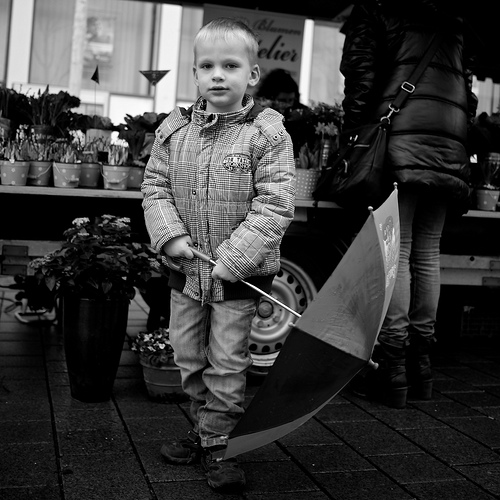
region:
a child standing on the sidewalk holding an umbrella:
[135, 16, 397, 453]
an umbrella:
[218, 205, 406, 475]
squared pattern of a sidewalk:
[335, 413, 485, 489]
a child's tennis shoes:
[158, 435, 243, 492]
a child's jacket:
[148, 102, 299, 283]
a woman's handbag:
[315, 110, 391, 210]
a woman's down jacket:
[350, 25, 477, 211]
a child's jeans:
[163, 296, 258, 442]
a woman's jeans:
[388, 200, 440, 343]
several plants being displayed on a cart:
[4, 87, 131, 184]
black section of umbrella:
[230, 313, 407, 442]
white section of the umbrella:
[303, 194, 418, 329]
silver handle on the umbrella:
[173, 224, 326, 337]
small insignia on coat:
[204, 146, 291, 188]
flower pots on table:
[20, 130, 145, 197]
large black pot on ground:
[38, 277, 144, 429]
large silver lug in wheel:
[258, 301, 281, 338]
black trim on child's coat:
[135, 258, 322, 310]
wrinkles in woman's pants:
[375, 228, 489, 307]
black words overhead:
[253, 25, 311, 70]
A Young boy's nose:
[208, 69, 228, 84]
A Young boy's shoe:
[206, 431, 243, 495]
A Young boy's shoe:
[161, 420, 207, 468]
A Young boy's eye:
[225, 59, 240, 72]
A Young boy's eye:
[201, 60, 216, 70]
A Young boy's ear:
[246, 65, 263, 90]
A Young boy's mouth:
[206, 82, 231, 99]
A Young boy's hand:
[207, 132, 302, 289]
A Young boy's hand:
[133, 140, 200, 271]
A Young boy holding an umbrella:
[148, 13, 412, 495]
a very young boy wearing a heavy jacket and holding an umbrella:
[113, 20, 320, 478]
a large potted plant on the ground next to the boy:
[23, 203, 162, 406]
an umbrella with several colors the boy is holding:
[209, 168, 417, 480]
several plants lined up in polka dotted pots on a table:
[4, 125, 144, 196]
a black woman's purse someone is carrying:
[325, 105, 392, 201]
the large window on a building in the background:
[20, 3, 164, 100]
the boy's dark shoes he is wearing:
[157, 434, 262, 496]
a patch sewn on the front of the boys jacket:
[216, 148, 255, 182]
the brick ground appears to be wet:
[343, 405, 489, 497]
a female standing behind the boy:
[330, 5, 486, 417]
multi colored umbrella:
[188, 176, 428, 467]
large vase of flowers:
[30, 207, 160, 414]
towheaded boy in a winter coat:
[154, 23, 299, 497]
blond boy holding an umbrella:
[139, 25, 426, 496]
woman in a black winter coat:
[331, 27, 479, 411]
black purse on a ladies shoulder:
[316, 109, 403, 203]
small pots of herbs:
[3, 99, 143, 184]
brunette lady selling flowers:
[262, 73, 319, 118]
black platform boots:
[371, 347, 448, 427]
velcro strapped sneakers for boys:
[153, 427, 273, 489]